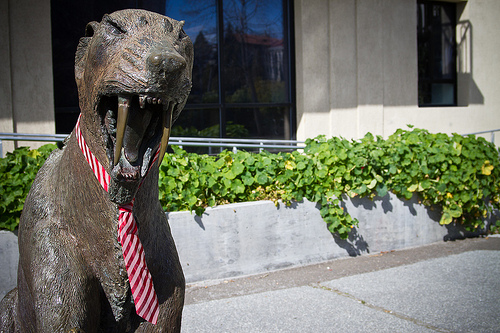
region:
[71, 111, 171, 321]
the tie around the statue's neck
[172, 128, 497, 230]
a green leafy plant sitting in the green planter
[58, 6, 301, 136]
the windows of the building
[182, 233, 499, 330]
a sidewalk for people to walk on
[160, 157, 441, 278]
a planter to hold different plants in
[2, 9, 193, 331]
the statue in front of the building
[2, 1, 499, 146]
the building in the back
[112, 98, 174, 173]
the long teeth on the statue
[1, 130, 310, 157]
the metal railings next to the ramp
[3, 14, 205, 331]
statue of animal on sidewalk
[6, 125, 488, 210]
plants in the concrete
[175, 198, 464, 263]
concrete wall alongside plants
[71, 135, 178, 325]
tie on the statue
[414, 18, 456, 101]
window to the building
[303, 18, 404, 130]
concrete between windows on building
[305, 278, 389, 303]
crack in the sidewalk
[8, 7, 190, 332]
a metal sculpture of a dog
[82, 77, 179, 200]
the dog sculpture has long spiked teeth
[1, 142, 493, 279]
a cement planter is behind the dog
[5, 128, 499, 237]
a green vine is growing in the planter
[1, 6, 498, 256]
a building is behind the sculpture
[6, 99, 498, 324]
the dog sculpture is on a sidewalk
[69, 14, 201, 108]
the ears are back on the dog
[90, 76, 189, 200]
the dog's mouth is wide open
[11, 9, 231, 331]
The statue of an animal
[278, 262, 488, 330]
The sidewalk is the color gray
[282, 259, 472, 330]
The sidewalk is made on asphalt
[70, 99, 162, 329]
The tie is the color red and white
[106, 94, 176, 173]
The teeth are very long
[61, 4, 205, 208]
The head of the statue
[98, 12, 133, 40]
The eye of the statue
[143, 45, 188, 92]
The nose of the statue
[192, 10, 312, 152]
The window on the side of the building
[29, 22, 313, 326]
a statue outside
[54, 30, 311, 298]
a statue ona sidewalk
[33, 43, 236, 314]
a tie on a statue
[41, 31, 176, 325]
a statue with a tie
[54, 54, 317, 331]
a statue with a red tie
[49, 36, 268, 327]
a red tie on a statue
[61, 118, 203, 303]
a red striped tie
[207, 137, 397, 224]
bushes on the sidewalk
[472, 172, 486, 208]
green leaves on the plants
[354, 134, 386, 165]
green leaves on the plants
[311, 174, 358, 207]
green leaves on the plants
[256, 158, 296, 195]
green leaves on the plants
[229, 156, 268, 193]
green leaves on the plants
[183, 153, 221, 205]
green leaves on the plants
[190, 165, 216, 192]
green leaves on the plants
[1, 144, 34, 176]
green leaves on the plants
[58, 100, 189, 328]
red and white striped tie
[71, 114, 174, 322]
red and white striped tie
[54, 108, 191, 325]
red and white striped tie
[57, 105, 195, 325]
red and white striped tie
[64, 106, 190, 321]
red and white striped tie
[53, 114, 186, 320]
red and white striped tie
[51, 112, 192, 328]
red and white striped tie